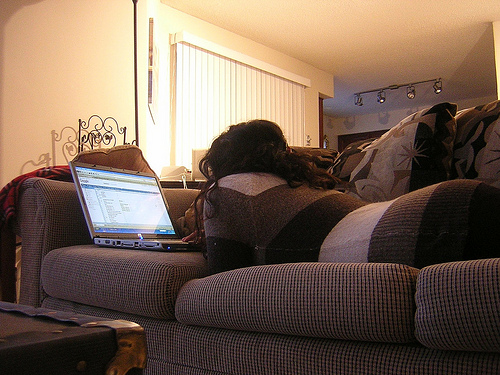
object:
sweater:
[197, 172, 485, 275]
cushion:
[40, 245, 208, 321]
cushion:
[173, 261, 415, 346]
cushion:
[413, 258, 499, 355]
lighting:
[352, 80, 441, 107]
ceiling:
[160, 0, 500, 119]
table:
[0, 301, 148, 375]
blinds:
[174, 40, 310, 171]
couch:
[14, 101, 498, 375]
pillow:
[70, 144, 160, 179]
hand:
[182, 229, 207, 247]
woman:
[178, 117, 500, 272]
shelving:
[76, 114, 127, 156]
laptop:
[69, 161, 205, 251]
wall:
[0, 0, 156, 197]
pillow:
[324, 102, 458, 204]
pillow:
[451, 100, 499, 188]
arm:
[204, 187, 251, 274]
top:
[77, 114, 139, 154]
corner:
[68, 317, 149, 374]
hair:
[192, 118, 353, 261]